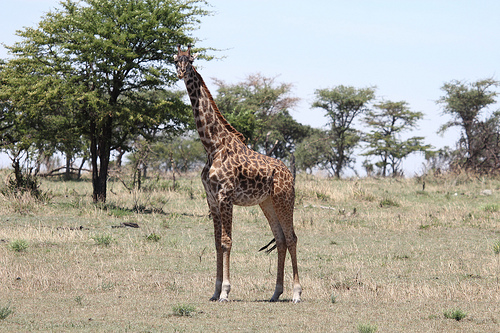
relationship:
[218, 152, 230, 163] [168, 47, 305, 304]
spot on giraffe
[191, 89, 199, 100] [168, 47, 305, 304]
spot on giraffe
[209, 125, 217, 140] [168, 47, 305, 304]
spot on giraffe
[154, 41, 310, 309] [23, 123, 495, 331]
giraffe in field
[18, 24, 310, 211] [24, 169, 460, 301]
trees on field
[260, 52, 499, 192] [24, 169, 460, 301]
trees on field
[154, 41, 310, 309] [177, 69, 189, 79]
giraffe has mouth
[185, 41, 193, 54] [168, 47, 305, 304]
horn on giraffe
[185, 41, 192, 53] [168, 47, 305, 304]
horn on giraffe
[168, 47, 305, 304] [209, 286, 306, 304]
giraffe has hooves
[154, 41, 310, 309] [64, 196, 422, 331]
giraffe in field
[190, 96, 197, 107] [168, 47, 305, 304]
spot on giraffe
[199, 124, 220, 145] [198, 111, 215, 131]
spot on giraffe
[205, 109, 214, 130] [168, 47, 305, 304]
spot on giraffe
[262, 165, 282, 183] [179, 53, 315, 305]
spot on giraffe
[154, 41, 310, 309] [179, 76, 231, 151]
giraffe has long neck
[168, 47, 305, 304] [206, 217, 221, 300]
giraffe has legs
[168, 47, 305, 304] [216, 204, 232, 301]
giraffe has legs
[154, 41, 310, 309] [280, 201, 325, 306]
giraffe has back legs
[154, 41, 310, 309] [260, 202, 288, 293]
giraffe has back legs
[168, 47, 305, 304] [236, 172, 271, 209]
giraffe has belly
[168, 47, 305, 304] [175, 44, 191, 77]
giraffe has head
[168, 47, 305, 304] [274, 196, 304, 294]
giraffe has back legs